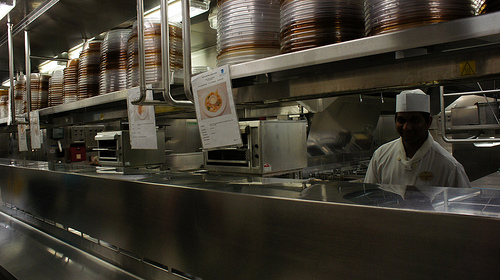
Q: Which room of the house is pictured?
A: It is a kitchen.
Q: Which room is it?
A: It is a kitchen.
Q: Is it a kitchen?
A: Yes, it is a kitchen.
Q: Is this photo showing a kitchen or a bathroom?
A: It is showing a kitchen.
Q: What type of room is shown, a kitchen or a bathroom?
A: It is a kitchen.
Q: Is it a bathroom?
A: No, it is a kitchen.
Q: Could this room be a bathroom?
A: No, it is a kitchen.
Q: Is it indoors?
A: Yes, it is indoors.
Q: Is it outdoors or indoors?
A: It is indoors.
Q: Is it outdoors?
A: No, it is indoors.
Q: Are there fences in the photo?
A: No, there are no fences.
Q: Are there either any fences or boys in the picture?
A: No, there are no fences or boys.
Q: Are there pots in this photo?
A: No, there are no pots.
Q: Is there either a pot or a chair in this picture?
A: No, there are no pots or chairs.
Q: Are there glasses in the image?
A: No, there are no glasses.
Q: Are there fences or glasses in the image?
A: No, there are no glasses or fences.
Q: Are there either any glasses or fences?
A: No, there are no glasses or fences.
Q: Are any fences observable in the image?
A: No, there are no fences.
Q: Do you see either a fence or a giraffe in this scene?
A: No, there are no fences or giraffes.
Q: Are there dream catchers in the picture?
A: No, there are no dream catchers.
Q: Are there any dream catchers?
A: No, there are no dream catchers.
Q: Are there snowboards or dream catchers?
A: No, there are no dream catchers or snowboards.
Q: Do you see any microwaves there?
A: Yes, there is a microwave.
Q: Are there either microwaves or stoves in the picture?
A: Yes, there is a microwave.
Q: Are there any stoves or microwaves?
A: Yes, there is a microwave.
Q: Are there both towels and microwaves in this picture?
A: No, there is a microwave but no towels.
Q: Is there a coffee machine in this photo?
A: No, there are no coffee makers.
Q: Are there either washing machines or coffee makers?
A: No, there are no coffee makers or washing machines.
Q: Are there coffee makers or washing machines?
A: No, there are no coffee makers or washing machines.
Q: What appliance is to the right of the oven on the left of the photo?
A: The appliance is a microwave.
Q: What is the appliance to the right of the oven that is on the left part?
A: The appliance is a microwave.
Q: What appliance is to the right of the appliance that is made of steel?
A: The appliance is a microwave.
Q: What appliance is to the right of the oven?
A: The appliance is a microwave.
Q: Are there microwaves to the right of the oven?
A: Yes, there is a microwave to the right of the oven.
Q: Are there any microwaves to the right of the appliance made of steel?
A: Yes, there is a microwave to the right of the oven.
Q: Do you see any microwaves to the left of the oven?
A: No, the microwave is to the right of the oven.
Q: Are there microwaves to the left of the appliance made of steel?
A: No, the microwave is to the right of the oven.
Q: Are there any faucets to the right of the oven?
A: No, there is a microwave to the right of the oven.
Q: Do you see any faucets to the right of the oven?
A: No, there is a microwave to the right of the oven.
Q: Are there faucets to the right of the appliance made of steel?
A: No, there is a microwave to the right of the oven.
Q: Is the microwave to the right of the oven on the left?
A: Yes, the microwave is to the right of the oven.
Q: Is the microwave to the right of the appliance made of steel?
A: Yes, the microwave is to the right of the oven.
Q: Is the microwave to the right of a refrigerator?
A: No, the microwave is to the right of the oven.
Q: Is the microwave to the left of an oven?
A: No, the microwave is to the right of an oven.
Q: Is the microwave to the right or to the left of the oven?
A: The microwave is to the right of the oven.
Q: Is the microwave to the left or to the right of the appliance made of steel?
A: The microwave is to the right of the oven.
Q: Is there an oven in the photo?
A: Yes, there is an oven.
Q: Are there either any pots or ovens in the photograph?
A: Yes, there is an oven.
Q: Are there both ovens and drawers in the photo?
A: No, there is an oven but no drawers.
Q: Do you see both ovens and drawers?
A: No, there is an oven but no drawers.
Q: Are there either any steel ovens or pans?
A: Yes, there is a steel oven.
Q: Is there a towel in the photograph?
A: No, there are no towels.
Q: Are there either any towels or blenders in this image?
A: No, there are no towels or blenders.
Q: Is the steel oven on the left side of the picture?
A: Yes, the oven is on the left of the image.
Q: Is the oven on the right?
A: No, the oven is on the left of the image.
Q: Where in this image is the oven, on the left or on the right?
A: The oven is on the left of the image.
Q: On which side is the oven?
A: The oven is on the left of the image.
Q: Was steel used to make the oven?
A: Yes, the oven is made of steel.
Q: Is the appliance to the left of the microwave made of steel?
A: Yes, the oven is made of steel.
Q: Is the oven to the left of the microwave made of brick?
A: No, the oven is made of steel.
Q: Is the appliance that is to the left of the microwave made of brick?
A: No, the oven is made of steel.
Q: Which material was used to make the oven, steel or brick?
A: The oven is made of steel.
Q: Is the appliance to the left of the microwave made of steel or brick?
A: The oven is made of steel.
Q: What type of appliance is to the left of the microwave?
A: The appliance is an oven.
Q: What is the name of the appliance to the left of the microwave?
A: The appliance is an oven.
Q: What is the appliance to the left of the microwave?
A: The appliance is an oven.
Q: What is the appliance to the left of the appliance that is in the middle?
A: The appliance is an oven.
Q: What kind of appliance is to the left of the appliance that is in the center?
A: The appliance is an oven.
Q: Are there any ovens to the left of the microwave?
A: Yes, there is an oven to the left of the microwave.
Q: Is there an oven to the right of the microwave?
A: No, the oven is to the left of the microwave.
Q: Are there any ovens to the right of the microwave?
A: No, the oven is to the left of the microwave.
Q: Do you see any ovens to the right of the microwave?
A: No, the oven is to the left of the microwave.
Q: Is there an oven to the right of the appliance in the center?
A: No, the oven is to the left of the microwave.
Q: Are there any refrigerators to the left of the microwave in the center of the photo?
A: No, there is an oven to the left of the microwave.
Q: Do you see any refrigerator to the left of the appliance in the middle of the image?
A: No, there is an oven to the left of the microwave.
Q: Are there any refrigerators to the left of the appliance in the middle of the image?
A: No, there is an oven to the left of the microwave.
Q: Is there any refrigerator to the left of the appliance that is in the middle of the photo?
A: No, there is an oven to the left of the microwave.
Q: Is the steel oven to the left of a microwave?
A: Yes, the oven is to the left of a microwave.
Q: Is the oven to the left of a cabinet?
A: No, the oven is to the left of a microwave.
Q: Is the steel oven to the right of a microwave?
A: No, the oven is to the left of a microwave.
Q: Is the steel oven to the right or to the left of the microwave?
A: The oven is to the left of the microwave.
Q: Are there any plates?
A: Yes, there is a plate.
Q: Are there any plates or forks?
A: Yes, there is a plate.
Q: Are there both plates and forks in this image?
A: No, there is a plate but no forks.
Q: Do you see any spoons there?
A: No, there are no spoons.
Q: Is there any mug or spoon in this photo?
A: No, there are no spoons or mugs.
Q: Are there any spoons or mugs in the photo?
A: No, there are no spoons or mugs.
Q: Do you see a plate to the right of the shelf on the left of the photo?
A: Yes, there is a plate to the right of the shelf.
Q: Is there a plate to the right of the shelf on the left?
A: Yes, there is a plate to the right of the shelf.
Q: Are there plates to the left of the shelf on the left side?
A: No, the plate is to the right of the shelf.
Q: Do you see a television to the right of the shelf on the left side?
A: No, there is a plate to the right of the shelf.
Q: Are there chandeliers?
A: No, there are no chandeliers.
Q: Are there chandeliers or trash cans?
A: No, there are no chandeliers or trash cans.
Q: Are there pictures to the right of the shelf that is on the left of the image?
A: Yes, there is a picture to the right of the shelf.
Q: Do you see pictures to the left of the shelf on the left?
A: No, the picture is to the right of the shelf.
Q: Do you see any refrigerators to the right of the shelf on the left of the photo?
A: No, there is a picture to the right of the shelf.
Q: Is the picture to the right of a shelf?
A: Yes, the picture is to the right of a shelf.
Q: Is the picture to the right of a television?
A: No, the picture is to the right of a shelf.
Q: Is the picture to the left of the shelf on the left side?
A: No, the picture is to the right of the shelf.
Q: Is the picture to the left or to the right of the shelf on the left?
A: The picture is to the right of the shelf.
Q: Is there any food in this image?
A: Yes, there is food.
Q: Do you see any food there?
A: Yes, there is food.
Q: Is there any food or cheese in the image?
A: Yes, there is food.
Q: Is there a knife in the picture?
A: No, there are no knives.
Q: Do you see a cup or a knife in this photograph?
A: No, there are no knives or cups.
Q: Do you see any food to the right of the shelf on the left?
A: Yes, there is food to the right of the shelf.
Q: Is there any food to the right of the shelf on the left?
A: Yes, there is food to the right of the shelf.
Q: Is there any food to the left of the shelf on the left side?
A: No, the food is to the right of the shelf.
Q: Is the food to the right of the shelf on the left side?
A: Yes, the food is to the right of the shelf.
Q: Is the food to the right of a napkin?
A: No, the food is to the right of the shelf.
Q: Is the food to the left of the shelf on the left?
A: No, the food is to the right of the shelf.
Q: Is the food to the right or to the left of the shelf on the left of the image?
A: The food is to the right of the shelf.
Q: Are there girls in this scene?
A: No, there are no girls.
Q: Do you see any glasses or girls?
A: No, there are no girls or glasses.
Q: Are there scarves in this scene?
A: Yes, there is a scarf.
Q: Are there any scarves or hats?
A: Yes, there is a scarf.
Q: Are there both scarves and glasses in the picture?
A: No, there is a scarf but no glasses.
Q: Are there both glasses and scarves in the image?
A: No, there is a scarf but no glasses.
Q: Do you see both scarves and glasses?
A: No, there is a scarf but no glasses.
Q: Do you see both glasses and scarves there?
A: No, there is a scarf but no glasses.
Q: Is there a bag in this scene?
A: No, there are no bags.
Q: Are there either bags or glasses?
A: No, there are no bags or glasses.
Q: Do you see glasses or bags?
A: No, there are no bags or glasses.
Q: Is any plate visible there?
A: Yes, there is a plate.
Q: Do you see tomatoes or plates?
A: Yes, there is a plate.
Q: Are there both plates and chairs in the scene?
A: No, there is a plate but no chairs.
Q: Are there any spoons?
A: No, there are no spoons.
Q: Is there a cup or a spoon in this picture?
A: No, there are no spoons or cups.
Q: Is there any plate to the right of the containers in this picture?
A: Yes, there is a plate to the right of the containers.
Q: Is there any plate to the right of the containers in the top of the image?
A: Yes, there is a plate to the right of the containers.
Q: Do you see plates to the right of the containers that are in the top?
A: Yes, there is a plate to the right of the containers.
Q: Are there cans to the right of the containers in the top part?
A: No, there is a plate to the right of the containers.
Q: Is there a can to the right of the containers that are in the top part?
A: No, there is a plate to the right of the containers.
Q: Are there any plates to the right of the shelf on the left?
A: Yes, there is a plate to the right of the shelf.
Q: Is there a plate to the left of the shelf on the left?
A: No, the plate is to the right of the shelf.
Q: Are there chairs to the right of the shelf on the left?
A: No, there is a plate to the right of the shelf.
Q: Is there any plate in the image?
A: Yes, there is a plate.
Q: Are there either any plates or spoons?
A: Yes, there is a plate.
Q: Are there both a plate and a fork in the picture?
A: No, there is a plate but no forks.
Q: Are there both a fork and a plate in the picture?
A: No, there is a plate but no forks.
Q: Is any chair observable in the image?
A: No, there are no chairs.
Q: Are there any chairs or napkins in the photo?
A: No, there are no chairs or napkins.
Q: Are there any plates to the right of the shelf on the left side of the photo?
A: Yes, there is a plate to the right of the shelf.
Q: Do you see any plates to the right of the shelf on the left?
A: Yes, there is a plate to the right of the shelf.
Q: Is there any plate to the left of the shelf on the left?
A: No, the plate is to the right of the shelf.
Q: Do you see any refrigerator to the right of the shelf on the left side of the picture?
A: No, there is a plate to the right of the shelf.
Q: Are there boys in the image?
A: No, there are no boys.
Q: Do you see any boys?
A: No, there are no boys.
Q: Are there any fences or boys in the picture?
A: No, there are no boys or fences.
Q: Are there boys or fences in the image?
A: No, there are no boys or fences.